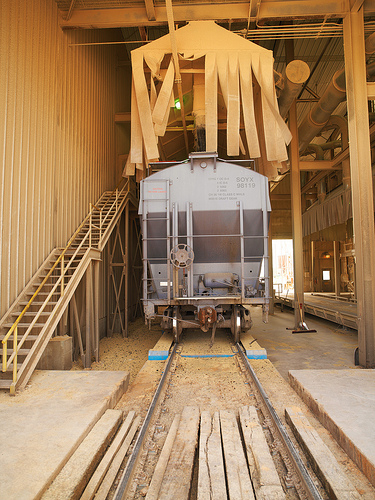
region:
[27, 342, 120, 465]
the ground is dusty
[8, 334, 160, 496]
the ground is dusty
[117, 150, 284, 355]
The train car is on the tracks.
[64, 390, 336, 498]
Pieces of wood are on the tracks.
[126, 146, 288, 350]
The train car is grey.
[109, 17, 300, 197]
A curtain is above the train.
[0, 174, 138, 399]
Stairs are beside the train.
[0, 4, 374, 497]
The train is inside a building.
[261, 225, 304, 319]
A door is visible.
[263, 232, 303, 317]
The door is open.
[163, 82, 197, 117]
A light is on the ceiling.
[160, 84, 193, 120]
The light is green.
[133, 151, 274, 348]
a grey train car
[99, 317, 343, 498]
a set of train tracks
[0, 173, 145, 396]
a tall tan staircase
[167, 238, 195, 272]
a grey turning wheel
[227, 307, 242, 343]
a silver train wheel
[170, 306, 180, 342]
a silver train wheel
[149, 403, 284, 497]
light brown wooden planks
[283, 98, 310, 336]
a tall metal supporting column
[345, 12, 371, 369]
a tall metal supporting column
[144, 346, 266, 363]
a blue spray painted line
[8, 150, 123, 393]
the stairs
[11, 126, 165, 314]
the stairs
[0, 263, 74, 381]
set of metal stairs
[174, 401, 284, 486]
wood planks laying on ground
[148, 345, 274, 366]
blue paint on wooden planks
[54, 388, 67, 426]
concrete platform near wooden planks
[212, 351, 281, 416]
steel track to move carrier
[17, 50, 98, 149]
metal corrugated wall is yellow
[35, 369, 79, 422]
dust and debris on concrete platform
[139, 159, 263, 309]
big gray carrier with wheels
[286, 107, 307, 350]
large steel support beam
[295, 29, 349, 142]
ceiling of metal corrugated building